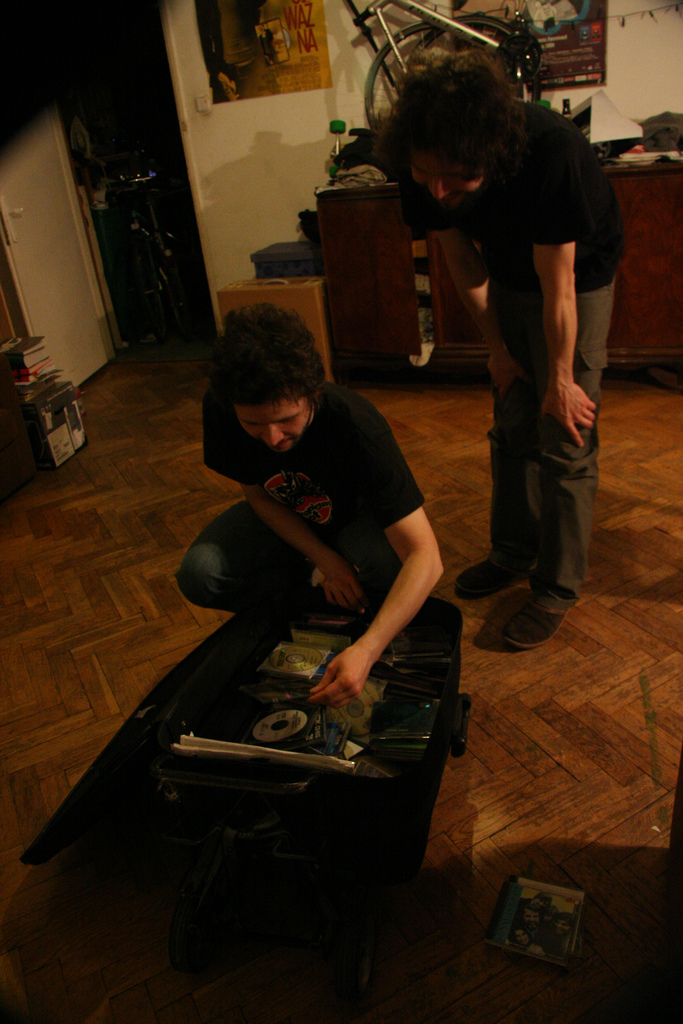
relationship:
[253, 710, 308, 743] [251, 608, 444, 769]
cd in luggage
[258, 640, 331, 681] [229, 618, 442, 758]
cd in luggage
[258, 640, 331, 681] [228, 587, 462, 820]
cd in luggage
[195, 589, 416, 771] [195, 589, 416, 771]
cd in luggage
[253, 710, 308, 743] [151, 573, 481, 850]
cd in luggage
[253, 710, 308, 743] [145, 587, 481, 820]
cd in luggage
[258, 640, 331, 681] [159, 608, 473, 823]
cd in luggage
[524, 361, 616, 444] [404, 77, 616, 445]
hand on man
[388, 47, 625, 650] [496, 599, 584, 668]
man wearing shoe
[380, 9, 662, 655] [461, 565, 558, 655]
man wearing shoe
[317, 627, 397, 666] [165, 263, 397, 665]
wrist on man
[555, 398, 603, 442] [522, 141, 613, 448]
fingers on hand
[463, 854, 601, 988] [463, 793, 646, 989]
cd on floor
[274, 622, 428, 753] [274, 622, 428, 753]
cd in luggage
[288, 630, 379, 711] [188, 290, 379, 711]
hand of a man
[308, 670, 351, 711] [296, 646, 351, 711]
fingers on a hand